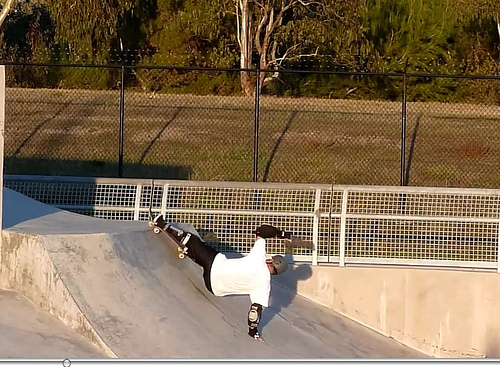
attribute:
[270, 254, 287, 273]
helmet — very hard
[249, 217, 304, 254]
band — black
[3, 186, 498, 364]
ground — sliding, brown, skate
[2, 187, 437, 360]
ramp — light gray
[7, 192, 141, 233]
deck — skateboard, dark grey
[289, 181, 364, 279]
pole — white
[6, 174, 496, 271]
wire fence — white, mesh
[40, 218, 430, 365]
ramp — concrete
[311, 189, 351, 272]
poles — white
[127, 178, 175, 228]
poles — white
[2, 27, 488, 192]
fence — mesh, wire, white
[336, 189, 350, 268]
pole — white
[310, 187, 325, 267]
pole — white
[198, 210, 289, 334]
tshirt — white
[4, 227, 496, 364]
ramp — off white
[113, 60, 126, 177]
pole — white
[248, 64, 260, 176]
pole — white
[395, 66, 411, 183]
pole — white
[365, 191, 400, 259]
fence — white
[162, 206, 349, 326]
man — skating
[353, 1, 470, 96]
tree — green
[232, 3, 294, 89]
trunk — light brown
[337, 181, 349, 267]
pole — white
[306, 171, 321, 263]
pole — white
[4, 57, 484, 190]
fence — black, wire, mesh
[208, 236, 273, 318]
shirt — white